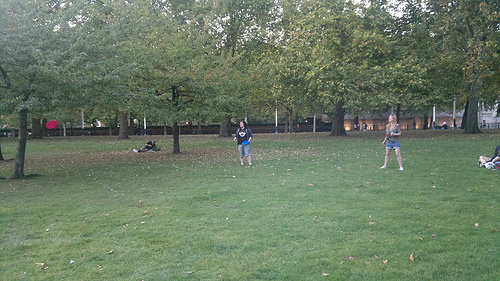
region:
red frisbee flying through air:
[44, 116, 58, 131]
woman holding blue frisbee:
[233, 118, 255, 168]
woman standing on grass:
[231, 120, 253, 167]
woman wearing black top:
[233, 117, 254, 165]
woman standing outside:
[380, 113, 405, 174]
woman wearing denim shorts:
[381, 113, 404, 173]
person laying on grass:
[132, 139, 162, 153]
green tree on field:
[113, 18, 235, 155]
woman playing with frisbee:
[376, 113, 406, 172]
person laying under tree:
[131, 140, 163, 154]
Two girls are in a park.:
[231, 108, 407, 176]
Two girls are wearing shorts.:
[225, 108, 409, 174]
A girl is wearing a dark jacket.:
[230, 117, 255, 148]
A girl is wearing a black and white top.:
[230, 115, 252, 143]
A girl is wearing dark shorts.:
[233, 140, 253, 160]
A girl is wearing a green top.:
[380, 116, 404, 146]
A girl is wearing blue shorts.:
[379, 135, 400, 151]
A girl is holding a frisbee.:
[235, 137, 251, 149]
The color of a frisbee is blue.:
[235, 135, 253, 150]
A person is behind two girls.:
[128, 134, 160, 157]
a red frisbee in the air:
[43, 118, 58, 130]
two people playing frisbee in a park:
[232, 110, 407, 172]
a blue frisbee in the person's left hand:
[241, 138, 249, 147]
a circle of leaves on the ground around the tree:
[42, 137, 316, 167]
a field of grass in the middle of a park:
[0, 128, 499, 279]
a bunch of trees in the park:
[0, 0, 497, 179]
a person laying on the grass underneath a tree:
[130, 137, 164, 153]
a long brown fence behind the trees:
[1, 123, 336, 135]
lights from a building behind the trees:
[342, 115, 449, 130]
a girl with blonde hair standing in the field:
[378, 109, 405, 172]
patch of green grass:
[124, 170, 359, 263]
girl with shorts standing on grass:
[382, 115, 403, 168]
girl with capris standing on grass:
[232, 118, 253, 169]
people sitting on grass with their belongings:
[481, 140, 499, 163]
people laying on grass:
[133, 137, 163, 154]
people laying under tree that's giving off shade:
[76, 13, 186, 153]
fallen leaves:
[74, 151, 215, 163]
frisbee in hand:
[241, 135, 249, 147]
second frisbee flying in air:
[36, 116, 62, 133]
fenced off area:
[4, 125, 331, 135]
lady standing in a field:
[372, 108, 420, 170]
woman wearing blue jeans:
[381, 134, 401, 151]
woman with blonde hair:
[381, 110, 397, 128]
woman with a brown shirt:
[379, 123, 401, 147]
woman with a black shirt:
[232, 127, 256, 141]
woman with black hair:
[233, 115, 248, 127]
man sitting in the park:
[126, 133, 166, 159]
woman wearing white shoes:
[373, 152, 415, 175]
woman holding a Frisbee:
[241, 137, 252, 148]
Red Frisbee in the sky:
[42, 108, 67, 145]